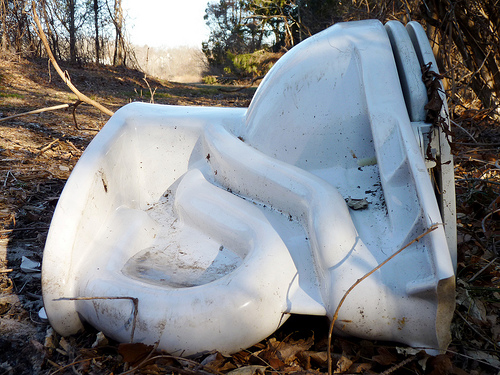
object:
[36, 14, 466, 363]
toilet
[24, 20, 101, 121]
stick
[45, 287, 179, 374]
branch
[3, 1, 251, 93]
woods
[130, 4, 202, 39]
sky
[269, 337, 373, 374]
leaves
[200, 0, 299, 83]
trees